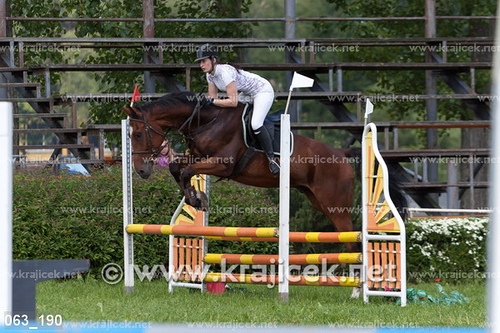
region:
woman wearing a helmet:
[188, 38, 278, 150]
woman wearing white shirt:
[180, 31, 270, 171]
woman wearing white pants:
[187, 41, 277, 164]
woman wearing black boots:
[185, 40, 280, 173]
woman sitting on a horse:
[186, 30, 279, 175]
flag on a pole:
[281, 73, 313, 124]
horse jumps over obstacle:
[110, 87, 360, 208]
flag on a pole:
[361, 95, 381, 125]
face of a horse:
[126, 101, 173, 186]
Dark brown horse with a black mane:
[124, 84, 357, 249]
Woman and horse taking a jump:
[123, 44, 373, 254]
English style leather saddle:
[241, 102, 283, 182]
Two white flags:
[281, 70, 373, 133]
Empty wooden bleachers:
[1, 0, 497, 211]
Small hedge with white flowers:
[405, 218, 490, 278]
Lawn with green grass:
[35, 274, 488, 325]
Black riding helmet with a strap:
[192, 44, 220, 74]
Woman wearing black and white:
[194, 46, 280, 176]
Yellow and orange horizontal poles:
[127, 219, 366, 289]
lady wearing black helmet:
[196, 47, 218, 74]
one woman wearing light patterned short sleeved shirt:
[194, 45, 261, 102]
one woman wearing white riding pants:
[194, 40, 286, 172]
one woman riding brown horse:
[122, 44, 369, 231]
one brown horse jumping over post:
[105, 87, 412, 302]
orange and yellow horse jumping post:
[116, 110, 409, 312]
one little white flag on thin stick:
[281, 65, 316, 125]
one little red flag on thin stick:
[123, 84, 143, 105]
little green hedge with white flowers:
[412, 214, 488, 285]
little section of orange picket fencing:
[362, 239, 404, 298]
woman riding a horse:
[191, 41, 281, 176]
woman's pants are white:
[240, 77, 275, 127]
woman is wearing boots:
[251, 112, 277, 172]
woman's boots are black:
[250, 120, 280, 175]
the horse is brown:
[120, 90, 352, 270]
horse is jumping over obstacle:
[100, 102, 410, 307]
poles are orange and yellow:
[130, 218, 362, 288]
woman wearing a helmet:
[190, 37, 222, 76]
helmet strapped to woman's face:
[195, 39, 222, 74]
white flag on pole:
[279, 69, 312, 113]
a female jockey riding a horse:
[194, 43, 279, 174]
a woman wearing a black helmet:
[192, 44, 278, 177]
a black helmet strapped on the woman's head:
[193, 43, 220, 74]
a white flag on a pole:
[280, 70, 314, 110]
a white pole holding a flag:
[277, 114, 291, 292]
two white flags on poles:
[284, 70, 374, 123]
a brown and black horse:
[125, 95, 410, 263]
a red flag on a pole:
[127, 83, 142, 104]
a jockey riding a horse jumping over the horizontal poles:
[122, 40, 410, 277]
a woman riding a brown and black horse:
[122, 44, 411, 306]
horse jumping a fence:
[118, 89, 406, 305]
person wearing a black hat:
[192, 42, 280, 176]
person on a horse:
[122, 41, 357, 253]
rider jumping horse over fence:
[118, 40, 407, 307]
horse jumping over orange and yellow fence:
[121, 90, 406, 306]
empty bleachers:
[0, 0, 497, 216]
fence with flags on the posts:
[120, 71, 409, 306]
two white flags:
[282, 70, 382, 125]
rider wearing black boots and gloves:
[195, 44, 279, 176]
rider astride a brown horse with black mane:
[123, 42, 358, 253]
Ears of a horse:
[119, 100, 141, 122]